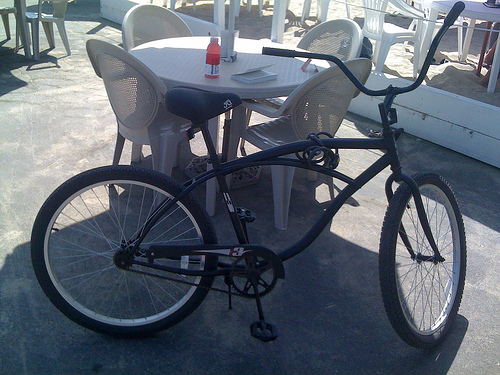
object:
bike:
[31, 1, 467, 350]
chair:
[226, 58, 372, 230]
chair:
[86, 38, 218, 211]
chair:
[121, 3, 195, 53]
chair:
[254, 19, 362, 110]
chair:
[361, 0, 425, 78]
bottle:
[204, 38, 222, 79]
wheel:
[30, 164, 218, 338]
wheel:
[378, 172, 467, 350]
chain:
[112, 248, 278, 298]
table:
[128, 36, 332, 88]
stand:
[186, 122, 263, 192]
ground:
[0, 0, 500, 375]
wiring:
[47, 183, 201, 323]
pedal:
[250, 320, 279, 342]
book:
[231, 64, 278, 85]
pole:
[271, 0, 286, 44]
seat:
[164, 85, 243, 120]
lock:
[295, 132, 339, 171]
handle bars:
[261, 0, 465, 96]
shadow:
[0, 150, 469, 375]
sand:
[137, 0, 500, 108]